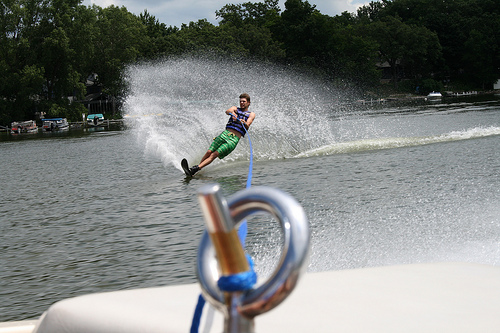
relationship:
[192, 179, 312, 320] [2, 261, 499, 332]
ring on boat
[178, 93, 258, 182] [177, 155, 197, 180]
man on water skiis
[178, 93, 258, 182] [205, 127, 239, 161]
man in swim trunks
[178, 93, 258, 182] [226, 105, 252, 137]
man in vest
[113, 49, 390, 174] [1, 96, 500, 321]
splash in water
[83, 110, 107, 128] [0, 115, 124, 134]
boat at dock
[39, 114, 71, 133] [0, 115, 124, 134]
boat at dock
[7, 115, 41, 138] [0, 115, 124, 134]
boat at dock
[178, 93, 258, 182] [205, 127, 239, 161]
man wears swim trunks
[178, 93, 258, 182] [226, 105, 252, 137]
man wears vest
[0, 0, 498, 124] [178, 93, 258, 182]
trees behind man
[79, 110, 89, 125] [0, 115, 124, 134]
pilings on dock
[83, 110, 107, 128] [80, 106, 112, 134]
boat on lift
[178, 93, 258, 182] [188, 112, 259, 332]
man has rope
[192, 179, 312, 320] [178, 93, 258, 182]
ring tows man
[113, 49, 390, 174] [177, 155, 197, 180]
splash from water skiis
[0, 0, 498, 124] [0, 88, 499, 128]
trees on shore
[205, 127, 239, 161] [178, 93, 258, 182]
swim trunks are on man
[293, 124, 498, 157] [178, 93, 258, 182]
wake behind man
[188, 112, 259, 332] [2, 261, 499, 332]
rope attached to boat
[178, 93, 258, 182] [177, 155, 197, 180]
man using one water ski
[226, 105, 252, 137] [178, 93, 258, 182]
vest on man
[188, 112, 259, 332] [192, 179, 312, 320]
rope tied around ring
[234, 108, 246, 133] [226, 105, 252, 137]
buckles on vest